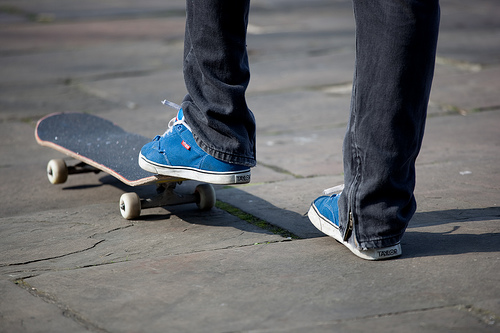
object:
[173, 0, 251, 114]
leg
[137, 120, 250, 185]
kicks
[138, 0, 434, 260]
person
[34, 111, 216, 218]
skateboard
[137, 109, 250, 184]
shoe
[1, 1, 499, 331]
ground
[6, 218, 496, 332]
stone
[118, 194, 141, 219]
wheels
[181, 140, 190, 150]
tag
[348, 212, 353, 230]
zipper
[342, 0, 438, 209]
jean leg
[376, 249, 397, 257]
taylor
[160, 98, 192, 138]
laces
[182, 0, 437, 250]
jeans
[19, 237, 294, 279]
cracks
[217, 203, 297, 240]
grass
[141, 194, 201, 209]
axel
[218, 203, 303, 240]
gap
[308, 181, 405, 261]
shoe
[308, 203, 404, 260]
rubber